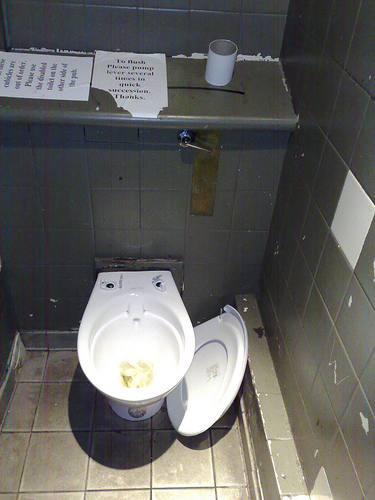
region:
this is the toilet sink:
[78, 281, 181, 405]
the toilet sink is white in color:
[79, 271, 187, 389]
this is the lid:
[198, 306, 249, 407]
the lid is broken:
[91, 270, 167, 300]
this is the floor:
[21, 419, 73, 497]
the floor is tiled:
[3, 420, 78, 496]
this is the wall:
[281, 187, 329, 252]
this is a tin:
[201, 40, 236, 81]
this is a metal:
[189, 136, 228, 206]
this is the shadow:
[100, 421, 154, 462]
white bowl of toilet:
[71, 251, 196, 380]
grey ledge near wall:
[229, 291, 310, 498]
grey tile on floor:
[42, 439, 178, 496]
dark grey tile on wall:
[92, 158, 152, 237]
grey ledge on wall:
[1, 38, 279, 130]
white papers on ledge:
[18, 41, 169, 117]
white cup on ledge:
[198, 37, 234, 86]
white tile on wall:
[289, 156, 373, 261]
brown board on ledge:
[165, 138, 235, 216]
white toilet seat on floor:
[187, 243, 245, 435]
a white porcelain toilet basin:
[73, 269, 195, 420]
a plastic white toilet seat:
[167, 303, 243, 436]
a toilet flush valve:
[175, 131, 213, 154]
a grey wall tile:
[87, 141, 141, 191]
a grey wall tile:
[34, 139, 85, 184]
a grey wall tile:
[0, 137, 36, 186]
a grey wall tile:
[0, 185, 45, 227]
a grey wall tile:
[37, 187, 94, 229]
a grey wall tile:
[89, 188, 140, 229]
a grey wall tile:
[140, 189, 186, 230]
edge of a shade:
[88, 446, 109, 479]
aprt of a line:
[77, 438, 106, 479]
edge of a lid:
[193, 404, 221, 443]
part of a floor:
[119, 457, 135, 475]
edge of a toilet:
[170, 481, 171, 483]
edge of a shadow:
[144, 440, 149, 446]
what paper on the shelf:
[90, 38, 174, 115]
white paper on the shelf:
[0, 40, 95, 115]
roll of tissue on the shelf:
[200, 31, 236, 86]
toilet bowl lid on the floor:
[186, 298, 257, 419]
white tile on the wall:
[314, 165, 374, 256]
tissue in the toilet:
[110, 348, 156, 394]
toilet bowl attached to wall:
[46, 247, 231, 442]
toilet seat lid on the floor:
[159, 299, 244, 449]